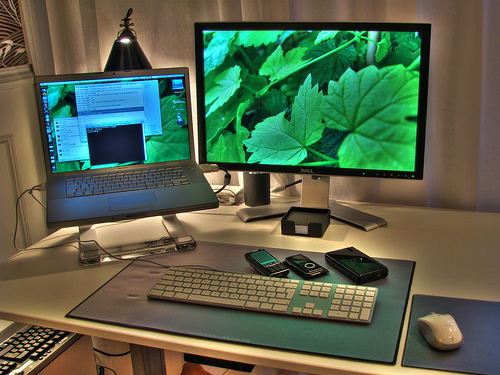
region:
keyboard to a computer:
[146, 257, 376, 349]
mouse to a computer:
[417, 310, 473, 357]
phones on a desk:
[239, 233, 338, 282]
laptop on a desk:
[31, 71, 214, 228]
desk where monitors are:
[405, 223, 496, 278]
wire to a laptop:
[16, 174, 50, 225]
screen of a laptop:
[48, 81, 186, 158]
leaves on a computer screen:
[216, 33, 389, 152]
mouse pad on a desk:
[467, 286, 494, 371]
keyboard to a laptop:
[1, 318, 73, 374]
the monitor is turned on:
[193, 20, 421, 176]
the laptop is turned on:
[36, 74, 199, 216]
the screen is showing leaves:
[203, 28, 418, 174]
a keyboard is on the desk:
[145, 263, 380, 327]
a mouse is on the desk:
[418, 310, 465, 350]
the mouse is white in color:
[418, 309, 465, 352]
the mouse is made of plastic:
[417, 309, 466, 351]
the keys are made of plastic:
[154, 262, 379, 324]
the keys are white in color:
[148, 264, 375, 324]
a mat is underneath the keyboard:
[72, 238, 418, 373]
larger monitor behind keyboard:
[182, 13, 432, 193]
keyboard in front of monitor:
[145, 260, 385, 336]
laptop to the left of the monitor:
[29, 59, 224, 235]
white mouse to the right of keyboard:
[408, 308, 466, 358]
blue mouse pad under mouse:
[397, 278, 499, 373]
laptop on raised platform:
[62, 194, 199, 274]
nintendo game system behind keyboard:
[323, 240, 394, 293]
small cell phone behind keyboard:
[284, 245, 327, 281]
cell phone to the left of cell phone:
[241, 240, 291, 282]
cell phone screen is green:
[243, 240, 293, 279]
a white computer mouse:
[414, 308, 464, 347]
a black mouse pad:
[400, 288, 499, 374]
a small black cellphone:
[240, 243, 287, 275]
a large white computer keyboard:
[146, 267, 378, 325]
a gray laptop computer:
[28, 64, 218, 227]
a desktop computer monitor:
[187, 20, 431, 180]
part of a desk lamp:
[98, 20, 154, 71]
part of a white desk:
[0, 185, 499, 373]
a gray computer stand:
[72, 213, 199, 261]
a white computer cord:
[7, 180, 44, 256]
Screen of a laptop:
[20, 71, 220, 172]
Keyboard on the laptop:
[70, 166, 190, 191]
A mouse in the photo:
[411, 296, 471, 356]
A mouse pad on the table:
[412, 288, 497, 368]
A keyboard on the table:
[143, 259, 376, 333]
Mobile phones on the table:
[232, 236, 382, 286]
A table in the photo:
[50, 264, 140, 330]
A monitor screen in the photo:
[199, 14, 421, 189]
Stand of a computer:
[70, 224, 240, 277]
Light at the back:
[100, 19, 184, 87]